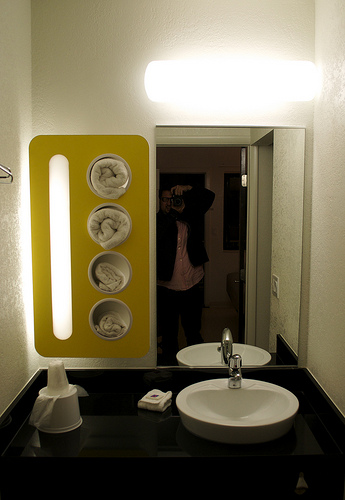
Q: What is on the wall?
A: Mirror.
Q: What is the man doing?
A: Taking a picture.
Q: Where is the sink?
A: Below mirror.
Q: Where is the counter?
A: Around sink.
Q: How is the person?
A: Taking pictures.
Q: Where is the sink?
A: In the bathroom.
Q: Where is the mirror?
A: In the bathroom.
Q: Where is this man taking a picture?
A: The bathroom.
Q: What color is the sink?
A: White.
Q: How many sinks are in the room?
A: 1.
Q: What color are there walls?
A: White.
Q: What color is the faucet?
A: Silver.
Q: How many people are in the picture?
A: 1.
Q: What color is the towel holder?
A: Yellow.